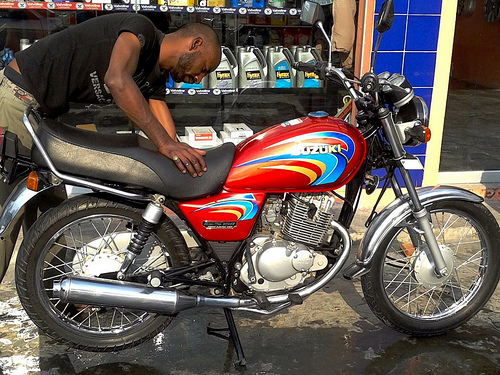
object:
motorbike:
[0, 1, 500, 366]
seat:
[21, 104, 238, 203]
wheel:
[16, 192, 193, 351]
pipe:
[50, 277, 199, 319]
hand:
[157, 141, 211, 178]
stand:
[208, 308, 247, 367]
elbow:
[101, 66, 134, 91]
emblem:
[288, 141, 342, 158]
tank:
[224, 110, 367, 194]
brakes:
[363, 166, 396, 228]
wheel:
[360, 200, 500, 338]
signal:
[27, 170, 44, 193]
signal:
[417, 124, 436, 144]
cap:
[305, 109, 330, 120]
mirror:
[300, 1, 318, 27]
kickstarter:
[148, 260, 228, 293]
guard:
[180, 192, 266, 242]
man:
[0, 12, 222, 214]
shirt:
[14, 12, 163, 119]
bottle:
[237, 44, 270, 88]